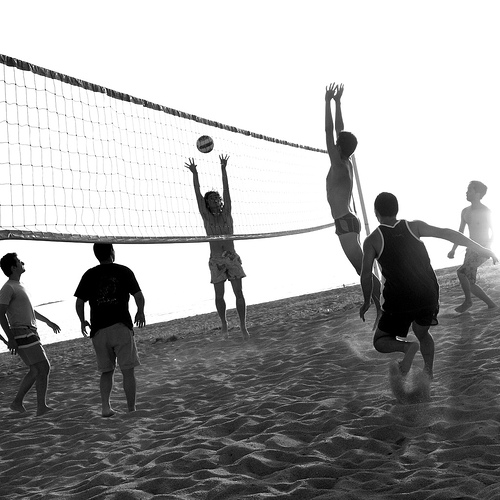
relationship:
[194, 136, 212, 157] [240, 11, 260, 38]
volleyball in sky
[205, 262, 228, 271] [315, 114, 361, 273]
swim trunks on man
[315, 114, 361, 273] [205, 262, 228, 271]
man wearing swim trunks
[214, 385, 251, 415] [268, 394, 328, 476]
ripples on beach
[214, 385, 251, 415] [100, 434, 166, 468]
ripples with footprints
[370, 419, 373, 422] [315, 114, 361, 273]
shadow of man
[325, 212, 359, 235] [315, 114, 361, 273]
speedo on man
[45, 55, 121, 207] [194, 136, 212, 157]
net for volleyball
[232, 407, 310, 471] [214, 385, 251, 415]
tracks on ripples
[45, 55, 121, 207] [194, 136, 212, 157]
net of volleyball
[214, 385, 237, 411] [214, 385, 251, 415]
ripples on ripples